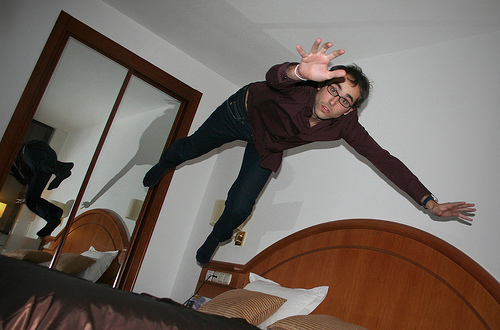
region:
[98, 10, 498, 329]
a man jumping on the bed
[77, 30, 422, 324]
a man in the air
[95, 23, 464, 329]
a man following on a bed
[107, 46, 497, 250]
a man wearing glasses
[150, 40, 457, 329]
a man wearing a shirt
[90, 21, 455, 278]
a man wearing a long sleeve shirt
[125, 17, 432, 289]
a man wearing jeans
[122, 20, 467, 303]
a man wearing blue jeans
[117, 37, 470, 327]
a man wearing socks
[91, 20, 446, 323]
a man wearing black socks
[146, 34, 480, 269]
man jumping on bed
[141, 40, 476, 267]
man wearing blue jeans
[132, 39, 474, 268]
man wearing black socks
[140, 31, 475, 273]
man wearing red shirt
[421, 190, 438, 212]
man wearing wrist watch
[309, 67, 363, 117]
man wearing black glasses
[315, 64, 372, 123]
man has brown hair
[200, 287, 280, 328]
striped pillow on bed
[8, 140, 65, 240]
man's reflection in mirror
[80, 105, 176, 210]
man shadow in mirror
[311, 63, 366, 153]
Man wearing glasses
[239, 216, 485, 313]
Curved wooden head board of bed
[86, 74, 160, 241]
Shadow on wall in mirrored door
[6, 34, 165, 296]
Closet with mirrored doors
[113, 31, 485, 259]
Man in air bouncing on bed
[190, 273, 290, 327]
Pillows on the bed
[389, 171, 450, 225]
Watch on man's wrist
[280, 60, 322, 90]
Man wearing a bracelet on his wrist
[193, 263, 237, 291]
Plugs on a wooden head board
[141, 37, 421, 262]
man with glass flying through the air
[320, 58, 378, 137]
man wearing black glasses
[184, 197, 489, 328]
light colored wooden headboard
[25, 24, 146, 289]
cabinet with mirror doors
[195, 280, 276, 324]
striped brown decorative pillow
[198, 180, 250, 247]
lamp that is mounted on the wall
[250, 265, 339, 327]
white cotton bed pillow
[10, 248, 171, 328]
dark brow shiny comforter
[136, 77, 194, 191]
reflection of the man's shadow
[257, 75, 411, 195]
maroon colored shirt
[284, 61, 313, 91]
He has a white bracelet on.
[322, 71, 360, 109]
He is wearing glasses.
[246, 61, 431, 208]
He has brown shoes on.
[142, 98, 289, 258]
The man has jeans on.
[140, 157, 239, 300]
The man has black socks.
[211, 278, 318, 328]
The pillows are tan and white.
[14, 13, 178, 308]
The mirror is large.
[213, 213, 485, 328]
The head board is brown.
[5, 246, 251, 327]
The covers are brown.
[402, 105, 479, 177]
The wall is white.